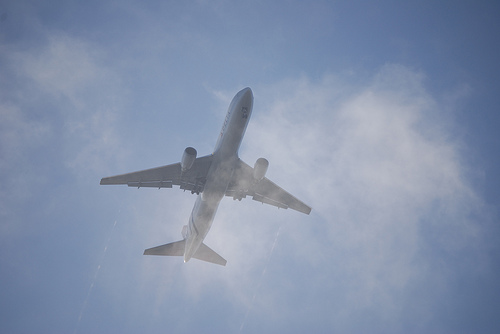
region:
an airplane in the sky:
[93, 84, 314, 273]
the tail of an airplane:
[137, 231, 234, 269]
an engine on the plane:
[176, 140, 201, 179]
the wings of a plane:
[94, 151, 319, 221]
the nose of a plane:
[229, 79, 261, 104]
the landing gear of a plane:
[236, 100, 252, 121]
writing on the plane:
[211, 105, 239, 145]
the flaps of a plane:
[122, 177, 177, 193]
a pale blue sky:
[0, 0, 498, 332]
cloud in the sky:
[0, 11, 130, 208]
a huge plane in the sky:
[37, 45, 448, 320]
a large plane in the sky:
[33, 33, 442, 314]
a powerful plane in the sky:
[4, 28, 447, 311]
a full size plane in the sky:
[22, 24, 434, 318]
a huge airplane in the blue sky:
[27, 8, 457, 288]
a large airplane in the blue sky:
[18, 46, 440, 298]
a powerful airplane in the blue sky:
[32, 28, 434, 323]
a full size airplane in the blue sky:
[46, 48, 413, 306]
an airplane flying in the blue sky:
[32, 13, 439, 303]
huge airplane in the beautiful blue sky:
[50, 46, 465, 316]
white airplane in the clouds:
[62, 71, 392, 306]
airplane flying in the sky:
[32, 18, 429, 313]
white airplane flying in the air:
[63, 65, 430, 301]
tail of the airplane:
[141, 235, 230, 267]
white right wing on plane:
[97, 146, 209, 197]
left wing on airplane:
[240, 155, 310, 215]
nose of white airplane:
[230, 82, 256, 97]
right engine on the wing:
[176, 140, 196, 170]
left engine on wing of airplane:
[250, 155, 270, 180]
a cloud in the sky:
[355, 95, 385, 132]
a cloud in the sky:
[212, 220, 249, 272]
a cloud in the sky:
[403, 148, 443, 214]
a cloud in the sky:
[62, 120, 99, 151]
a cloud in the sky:
[33, 27, 85, 87]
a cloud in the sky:
[66, 107, 106, 187]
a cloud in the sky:
[351, 245, 423, 302]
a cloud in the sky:
[445, 62, 480, 137]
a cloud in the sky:
[136, 208, 168, 235]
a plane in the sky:
[106, 77, 316, 284]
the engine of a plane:
[245, 151, 275, 186]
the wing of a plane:
[93, 146, 215, 213]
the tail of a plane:
[136, 239, 230, 269]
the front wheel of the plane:
[236, 100, 253, 124]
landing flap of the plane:
[124, 176, 176, 192]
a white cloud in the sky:
[2, 5, 150, 199]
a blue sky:
[0, 5, 498, 330]